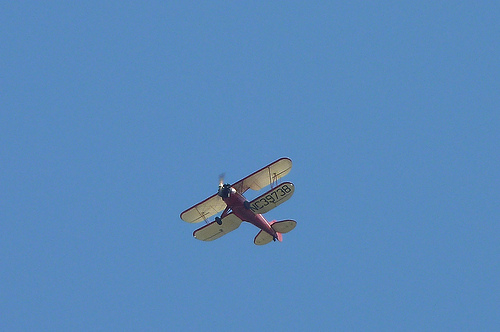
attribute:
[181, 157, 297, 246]
biplane — white, red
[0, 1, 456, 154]
sky — blue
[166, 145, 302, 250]
plane — one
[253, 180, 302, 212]
wing — one, plane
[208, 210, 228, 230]
wheel — one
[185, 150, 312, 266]
plane — one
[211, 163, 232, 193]
propeller — one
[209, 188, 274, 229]
wheels — landing, black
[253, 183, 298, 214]
numbers — black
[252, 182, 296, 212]
letters — black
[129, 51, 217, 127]
sky — vast, clear, blue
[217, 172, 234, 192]
propeller — spinning, airplane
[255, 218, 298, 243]
wings — small, white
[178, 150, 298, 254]
airplane — red, white , one, small, creme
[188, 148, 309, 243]
airplane — one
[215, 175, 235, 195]
engine — propeller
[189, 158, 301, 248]
airplane — one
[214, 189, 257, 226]
wheels — black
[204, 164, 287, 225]
rods — metal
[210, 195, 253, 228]
landing gear — fixed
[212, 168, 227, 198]
propeller — pictured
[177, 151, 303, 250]
plane — one, flying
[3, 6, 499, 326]
sky — blue, clear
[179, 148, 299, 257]
plane — red, white